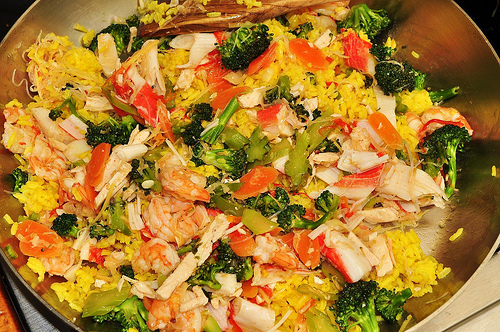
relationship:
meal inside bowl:
[5, 0, 473, 332] [2, 0, 500, 331]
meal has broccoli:
[5, 0, 473, 332] [213, 22, 274, 70]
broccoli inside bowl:
[413, 123, 467, 197] [2, 0, 500, 331]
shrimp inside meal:
[149, 192, 203, 241] [5, 0, 473, 332]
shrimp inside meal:
[161, 165, 214, 204] [5, 0, 473, 332]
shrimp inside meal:
[133, 238, 180, 274] [5, 0, 473, 332]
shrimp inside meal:
[149, 287, 199, 331] [5, 0, 473, 332]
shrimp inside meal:
[423, 103, 472, 138] [5, 0, 473, 332]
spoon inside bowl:
[138, 0, 346, 36] [2, 0, 500, 331]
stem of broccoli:
[356, 312, 377, 331] [334, 280, 378, 331]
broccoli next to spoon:
[213, 22, 274, 70] [138, 0, 346, 36]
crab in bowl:
[342, 28, 376, 77] [2, 0, 500, 331]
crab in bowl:
[316, 229, 371, 281] [2, 0, 500, 331]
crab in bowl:
[325, 163, 383, 199] [2, 0, 500, 331]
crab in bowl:
[128, 79, 157, 127] [2, 0, 500, 331]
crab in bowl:
[383, 163, 446, 204] [2, 0, 500, 331]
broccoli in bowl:
[84, 117, 133, 146] [2, 0, 500, 331]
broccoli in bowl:
[50, 212, 79, 238] [2, 0, 500, 331]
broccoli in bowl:
[94, 295, 148, 331] [2, 0, 500, 331]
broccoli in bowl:
[375, 56, 428, 95] [2, 0, 500, 331]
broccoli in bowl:
[336, 2, 390, 38] [2, 0, 500, 331]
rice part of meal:
[370, 226, 438, 294] [5, 0, 473, 332]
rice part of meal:
[15, 176, 60, 213] [5, 0, 473, 332]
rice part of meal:
[50, 264, 94, 312] [5, 0, 473, 332]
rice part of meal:
[27, 257, 48, 283] [5, 0, 473, 332]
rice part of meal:
[448, 225, 463, 242] [5, 0, 473, 332]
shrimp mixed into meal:
[161, 165, 214, 204] [5, 0, 473, 332]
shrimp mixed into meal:
[149, 192, 203, 241] [5, 0, 473, 332]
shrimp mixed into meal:
[133, 238, 180, 274] [5, 0, 473, 332]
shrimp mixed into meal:
[423, 103, 472, 138] [5, 0, 473, 332]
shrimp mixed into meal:
[149, 287, 199, 331] [5, 0, 473, 332]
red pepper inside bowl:
[140, 227, 153, 241] [2, 0, 500, 331]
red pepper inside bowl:
[212, 84, 248, 108] [2, 0, 500, 331]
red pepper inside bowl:
[247, 42, 277, 77] [2, 0, 500, 331]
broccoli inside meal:
[90, 21, 129, 60] [5, 0, 473, 332]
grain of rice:
[54, 35, 70, 46] [27, 31, 105, 97]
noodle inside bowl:
[402, 138, 423, 218] [2, 0, 500, 331]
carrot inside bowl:
[368, 111, 404, 148] [2, 0, 500, 331]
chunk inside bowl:
[159, 251, 198, 299] [2, 0, 500, 331]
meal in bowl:
[5, 0, 473, 332] [2, 0, 500, 331]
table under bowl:
[2, 270, 79, 331] [2, 0, 500, 331]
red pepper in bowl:
[140, 227, 153, 241] [2, 0, 500, 331]